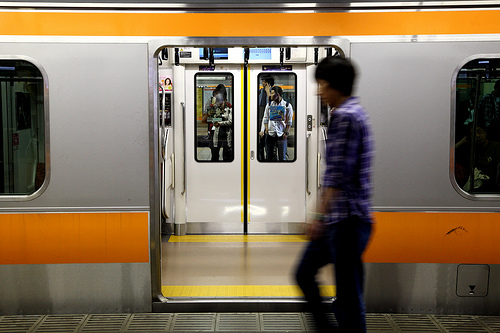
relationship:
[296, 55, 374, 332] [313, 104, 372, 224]
man wearing shirt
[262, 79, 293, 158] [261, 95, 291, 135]
person wearing shirt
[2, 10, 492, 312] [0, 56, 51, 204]
train has window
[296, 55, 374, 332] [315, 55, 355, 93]
man has hair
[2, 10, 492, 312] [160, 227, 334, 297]
train has floor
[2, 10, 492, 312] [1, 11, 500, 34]
train has stripe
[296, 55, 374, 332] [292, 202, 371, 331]
man wearing pants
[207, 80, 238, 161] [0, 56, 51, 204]
person inside of window